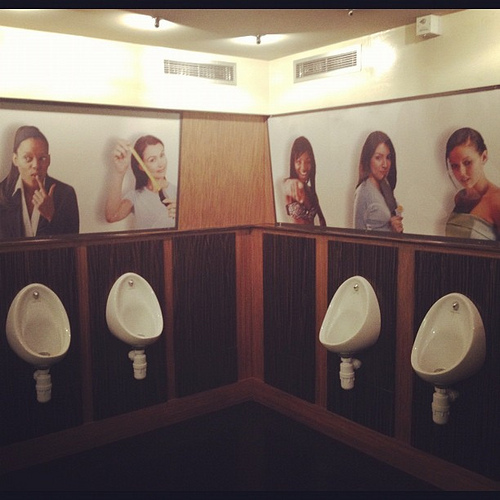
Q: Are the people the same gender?
A: Yes, all the people are female.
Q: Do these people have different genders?
A: No, all the people are female.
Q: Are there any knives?
A: Yes, there is a knife.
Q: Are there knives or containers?
A: Yes, there is a knife.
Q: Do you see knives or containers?
A: Yes, there is a knife.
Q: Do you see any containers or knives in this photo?
A: Yes, there is a knife.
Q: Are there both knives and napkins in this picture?
A: No, there is a knife but no napkins.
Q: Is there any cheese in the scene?
A: No, there is no cheese.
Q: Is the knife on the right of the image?
A: Yes, the knife is on the right of the image.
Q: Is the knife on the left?
A: No, the knife is on the right of the image.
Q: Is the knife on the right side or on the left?
A: The knife is on the right of the image.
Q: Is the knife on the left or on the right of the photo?
A: The knife is on the right of the image.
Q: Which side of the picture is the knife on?
A: The knife is on the right of the image.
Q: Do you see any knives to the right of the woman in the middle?
A: Yes, there is a knife to the right of the woman.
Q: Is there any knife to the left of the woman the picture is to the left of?
A: No, the knife is to the right of the woman.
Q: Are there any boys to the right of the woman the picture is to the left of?
A: No, there is a knife to the right of the woman.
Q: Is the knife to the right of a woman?
A: Yes, the knife is to the right of a woman.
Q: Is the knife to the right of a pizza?
A: No, the knife is to the right of a woman.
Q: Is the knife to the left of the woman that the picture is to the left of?
A: No, the knife is to the right of the woman.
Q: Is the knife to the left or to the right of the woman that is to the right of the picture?
A: The knife is to the right of the woman.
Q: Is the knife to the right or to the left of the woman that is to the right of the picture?
A: The knife is to the right of the woman.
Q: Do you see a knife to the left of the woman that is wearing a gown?
A: Yes, there is a knife to the left of the woman.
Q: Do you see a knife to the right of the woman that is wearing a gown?
A: No, the knife is to the left of the woman.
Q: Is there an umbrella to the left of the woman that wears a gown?
A: No, there is a knife to the left of the woman.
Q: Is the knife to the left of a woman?
A: Yes, the knife is to the left of a woman.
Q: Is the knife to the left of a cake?
A: No, the knife is to the left of a woman.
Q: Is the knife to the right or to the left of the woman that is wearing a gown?
A: The knife is to the left of the woman.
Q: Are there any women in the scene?
A: Yes, there is a woman.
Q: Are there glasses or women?
A: Yes, there is a woman.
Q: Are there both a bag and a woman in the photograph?
A: No, there is a woman but no bags.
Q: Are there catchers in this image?
A: No, there are no catchers.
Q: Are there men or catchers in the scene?
A: No, there are no catchers or men.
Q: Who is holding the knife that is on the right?
A: The woman is holding the knife.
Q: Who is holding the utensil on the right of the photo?
A: The woman is holding the knife.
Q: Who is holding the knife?
A: The woman is holding the knife.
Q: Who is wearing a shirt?
A: The woman is wearing a shirt.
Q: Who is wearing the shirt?
A: The woman is wearing a shirt.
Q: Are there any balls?
A: No, there are no balls.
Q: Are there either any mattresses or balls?
A: No, there are no balls or mattresses.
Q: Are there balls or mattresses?
A: No, there are no balls or mattresses.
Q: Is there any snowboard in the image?
A: No, there are no snowboards.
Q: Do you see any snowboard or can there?
A: No, there are no snowboards or cans.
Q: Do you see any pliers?
A: No, there are no pliers.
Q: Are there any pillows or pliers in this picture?
A: No, there are no pliers or pillows.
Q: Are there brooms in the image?
A: No, there are no brooms.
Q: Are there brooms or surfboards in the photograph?
A: No, there are no brooms or surfboards.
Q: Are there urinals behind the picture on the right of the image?
A: Yes, there is a urinal behind the picture.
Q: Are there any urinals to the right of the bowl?
A: Yes, there is a urinal to the right of the bowl.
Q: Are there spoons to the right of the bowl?
A: No, there is a urinal to the right of the bowl.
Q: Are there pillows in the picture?
A: No, there are no pillows.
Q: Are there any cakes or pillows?
A: No, there are no pillows or cakes.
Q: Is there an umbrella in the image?
A: No, there are no umbrellas.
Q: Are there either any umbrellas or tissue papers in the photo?
A: No, there are no umbrellas or tissue papers.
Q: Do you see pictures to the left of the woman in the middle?
A: Yes, there is a picture to the left of the woman.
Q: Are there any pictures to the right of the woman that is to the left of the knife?
A: No, the picture is to the left of the woman.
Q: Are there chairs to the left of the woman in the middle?
A: No, there is a picture to the left of the woman.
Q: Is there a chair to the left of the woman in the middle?
A: No, there is a picture to the left of the woman.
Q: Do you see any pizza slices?
A: No, there are no pizza slices.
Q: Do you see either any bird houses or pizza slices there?
A: No, there are no pizza slices or bird houses.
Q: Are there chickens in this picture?
A: No, there are no chickens.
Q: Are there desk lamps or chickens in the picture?
A: No, there are no chickens or desk lamps.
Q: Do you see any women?
A: Yes, there is a woman.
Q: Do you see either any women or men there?
A: Yes, there is a woman.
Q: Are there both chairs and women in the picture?
A: No, there is a woman but no chairs.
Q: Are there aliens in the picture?
A: No, there are no aliens.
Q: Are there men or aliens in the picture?
A: No, there are no aliens or men.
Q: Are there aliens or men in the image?
A: No, there are no aliens or men.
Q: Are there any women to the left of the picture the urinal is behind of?
A: Yes, there is a woman to the left of the picture.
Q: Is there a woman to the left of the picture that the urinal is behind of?
A: Yes, there is a woman to the left of the picture.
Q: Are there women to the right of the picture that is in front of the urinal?
A: No, the woman is to the left of the picture.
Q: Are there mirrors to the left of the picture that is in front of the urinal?
A: No, there is a woman to the left of the picture.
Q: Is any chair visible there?
A: No, there are no chairs.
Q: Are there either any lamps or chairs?
A: No, there are no chairs or lamps.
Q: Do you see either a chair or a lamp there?
A: No, there are no chairs or lamps.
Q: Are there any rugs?
A: No, there are no rugs.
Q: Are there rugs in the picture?
A: No, there are no rugs.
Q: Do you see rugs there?
A: No, there are no rugs.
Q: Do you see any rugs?
A: No, there are no rugs.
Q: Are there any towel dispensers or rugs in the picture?
A: No, there are no rugs or towel dispensers.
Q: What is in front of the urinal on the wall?
A: The picture is in front of the urinal.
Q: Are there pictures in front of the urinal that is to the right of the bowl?
A: Yes, there is a picture in front of the urinal.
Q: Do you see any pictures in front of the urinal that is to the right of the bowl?
A: Yes, there is a picture in front of the urinal.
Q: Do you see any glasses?
A: No, there are no glasses.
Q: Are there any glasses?
A: No, there are no glasses.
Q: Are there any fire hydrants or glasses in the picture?
A: No, there are no glasses or fire hydrants.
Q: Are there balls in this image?
A: No, there are no balls.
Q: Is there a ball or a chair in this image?
A: No, there are no balls or chairs.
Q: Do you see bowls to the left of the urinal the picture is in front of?
A: Yes, there is a bowl to the left of the urinal.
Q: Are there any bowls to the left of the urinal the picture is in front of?
A: Yes, there is a bowl to the left of the urinal.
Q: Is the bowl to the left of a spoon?
A: No, the bowl is to the left of the urinal.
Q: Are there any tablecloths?
A: No, there are no tablecloths.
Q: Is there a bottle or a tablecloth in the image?
A: No, there are no tablecloths or bottles.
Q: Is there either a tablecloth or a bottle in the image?
A: No, there are no tablecloths or bottles.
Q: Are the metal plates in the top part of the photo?
A: Yes, the plates are in the top of the image.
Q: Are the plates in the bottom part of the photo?
A: No, the plates are in the top of the image.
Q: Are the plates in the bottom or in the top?
A: The plates are in the top of the image.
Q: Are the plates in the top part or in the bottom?
A: The plates are in the top of the image.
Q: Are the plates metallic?
A: Yes, the plates are metallic.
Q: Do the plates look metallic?
A: Yes, the plates are metallic.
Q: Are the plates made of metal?
A: Yes, the plates are made of metal.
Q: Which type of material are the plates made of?
A: The plates are made of metal.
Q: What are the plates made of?
A: The plates are made of metal.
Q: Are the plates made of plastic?
A: No, the plates are made of metal.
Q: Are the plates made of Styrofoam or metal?
A: The plates are made of metal.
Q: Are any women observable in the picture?
A: Yes, there is a woman.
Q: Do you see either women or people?
A: Yes, there is a woman.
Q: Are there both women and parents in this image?
A: No, there is a woman but no parents.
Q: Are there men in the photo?
A: No, there are no men.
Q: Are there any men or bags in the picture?
A: No, there are no men or bags.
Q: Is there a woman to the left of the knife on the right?
A: Yes, there is a woman to the left of the knife.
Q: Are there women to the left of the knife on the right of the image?
A: Yes, there is a woman to the left of the knife.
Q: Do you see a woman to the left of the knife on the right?
A: Yes, there is a woman to the left of the knife.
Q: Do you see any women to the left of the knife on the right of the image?
A: Yes, there is a woman to the left of the knife.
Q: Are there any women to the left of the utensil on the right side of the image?
A: Yes, there is a woman to the left of the knife.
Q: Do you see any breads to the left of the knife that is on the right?
A: No, there is a woman to the left of the knife.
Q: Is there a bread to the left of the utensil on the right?
A: No, there is a woman to the left of the knife.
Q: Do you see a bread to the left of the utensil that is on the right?
A: No, there is a woman to the left of the knife.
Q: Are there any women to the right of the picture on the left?
A: Yes, there is a woman to the right of the picture.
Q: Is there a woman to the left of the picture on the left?
A: No, the woman is to the right of the picture.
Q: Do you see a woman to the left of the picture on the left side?
A: No, the woman is to the right of the picture.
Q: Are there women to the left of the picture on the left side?
A: No, the woman is to the right of the picture.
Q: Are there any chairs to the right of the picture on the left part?
A: No, there is a woman to the right of the picture.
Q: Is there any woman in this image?
A: Yes, there are women.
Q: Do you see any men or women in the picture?
A: Yes, there are women.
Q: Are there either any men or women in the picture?
A: Yes, there are women.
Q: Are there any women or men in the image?
A: Yes, there are women.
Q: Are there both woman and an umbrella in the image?
A: No, there are women but no umbrellas.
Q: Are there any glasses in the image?
A: No, there are no glasses.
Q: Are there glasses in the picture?
A: No, there are no glasses.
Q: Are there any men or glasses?
A: No, there are no glasses or men.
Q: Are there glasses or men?
A: No, there are no glasses or men.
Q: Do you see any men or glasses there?
A: No, there are no glasses or men.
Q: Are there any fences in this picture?
A: No, there are no fences.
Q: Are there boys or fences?
A: No, there are no fences or boys.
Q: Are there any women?
A: Yes, there is a woman.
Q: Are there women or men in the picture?
A: Yes, there is a woman.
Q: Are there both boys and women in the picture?
A: No, there is a woman but no boys.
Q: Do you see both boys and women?
A: No, there is a woman but no boys.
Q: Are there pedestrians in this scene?
A: No, there are no pedestrians.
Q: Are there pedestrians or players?
A: No, there are no pedestrians or players.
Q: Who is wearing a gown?
A: The woman is wearing a gown.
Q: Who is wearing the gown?
A: The woman is wearing a gown.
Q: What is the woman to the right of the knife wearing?
A: The woman is wearing a gown.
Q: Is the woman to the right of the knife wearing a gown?
A: Yes, the woman is wearing a gown.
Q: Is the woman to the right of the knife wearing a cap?
A: No, the woman is wearing a gown.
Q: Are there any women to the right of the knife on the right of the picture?
A: Yes, there is a woman to the right of the knife.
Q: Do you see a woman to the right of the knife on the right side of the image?
A: Yes, there is a woman to the right of the knife.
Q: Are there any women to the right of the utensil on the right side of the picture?
A: Yes, there is a woman to the right of the knife.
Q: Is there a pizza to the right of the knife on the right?
A: No, there is a woman to the right of the knife.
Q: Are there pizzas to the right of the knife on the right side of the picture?
A: No, there is a woman to the right of the knife.